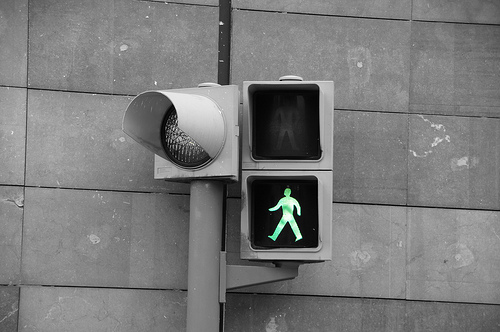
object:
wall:
[0, 1, 500, 332]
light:
[120, 88, 227, 169]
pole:
[185, 180, 224, 331]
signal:
[240, 80, 333, 261]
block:
[0, 0, 28, 87]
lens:
[159, 106, 211, 168]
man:
[271, 97, 302, 153]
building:
[0, 0, 499, 332]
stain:
[403, 113, 454, 160]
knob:
[278, 75, 304, 80]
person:
[266, 188, 304, 242]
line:
[217, 0, 232, 84]